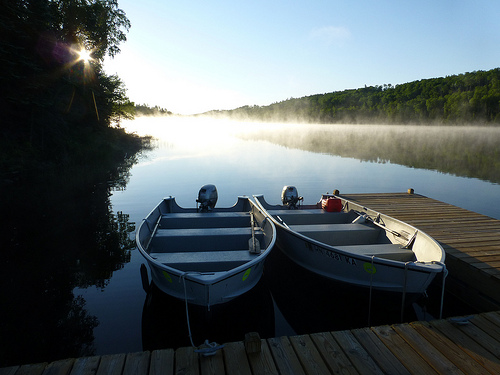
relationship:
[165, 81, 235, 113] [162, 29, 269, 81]
clouds in sky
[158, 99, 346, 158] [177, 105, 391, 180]
steam over lake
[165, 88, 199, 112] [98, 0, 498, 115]
clouds in sky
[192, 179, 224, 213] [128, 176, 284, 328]
motor on boat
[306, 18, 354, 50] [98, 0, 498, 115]
clouds in sky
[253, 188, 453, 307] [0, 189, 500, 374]
boat moored at dock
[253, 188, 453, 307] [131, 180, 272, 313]
boat beside boat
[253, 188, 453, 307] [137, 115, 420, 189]
boat in water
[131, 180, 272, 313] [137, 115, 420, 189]
boat in water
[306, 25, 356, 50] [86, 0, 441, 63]
clouds in sky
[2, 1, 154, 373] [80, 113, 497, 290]
trees seen in water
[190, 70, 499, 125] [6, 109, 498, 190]
tree lining edge of water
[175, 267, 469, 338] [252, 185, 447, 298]
ropes hang over boat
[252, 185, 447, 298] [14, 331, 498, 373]
boat near dock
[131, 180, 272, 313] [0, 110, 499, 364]
boat in water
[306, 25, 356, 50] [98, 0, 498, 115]
clouds in sky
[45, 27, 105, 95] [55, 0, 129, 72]
sunlight through leaves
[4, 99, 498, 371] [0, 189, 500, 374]
scene of dock